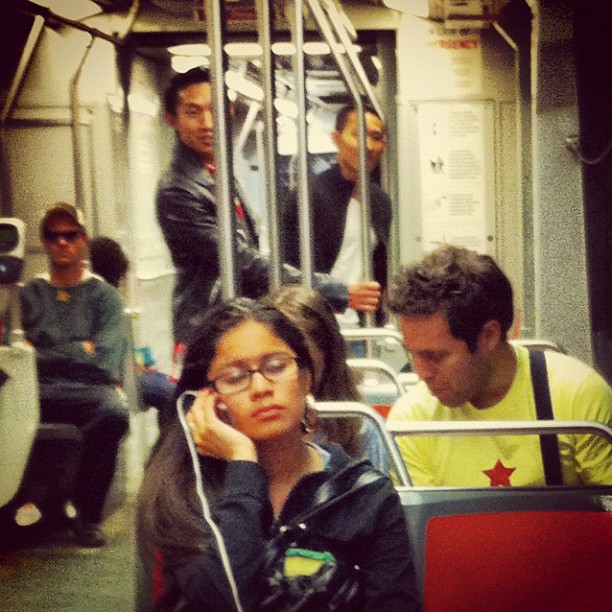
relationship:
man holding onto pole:
[153, 65, 381, 346] [293, 69, 311, 291]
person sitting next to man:
[260, 282, 392, 487] [380, 240, 612, 485]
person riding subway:
[260, 282, 392, 487] [2, 3, 592, 609]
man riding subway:
[380, 240, 612, 485] [2, 3, 592, 609]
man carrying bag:
[380, 245, 609, 487] [526, 344, 564, 486]